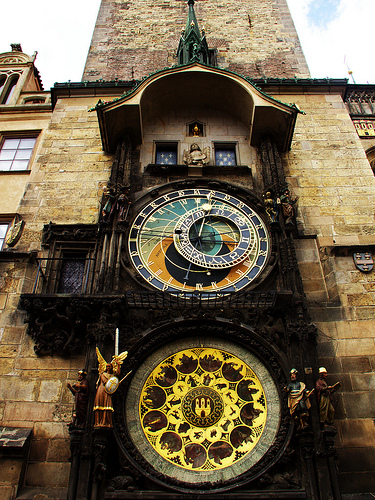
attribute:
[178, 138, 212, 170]
angel — gold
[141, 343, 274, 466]
clock — gold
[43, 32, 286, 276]
castle — huge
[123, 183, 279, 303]
clock — large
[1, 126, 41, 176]
window — closed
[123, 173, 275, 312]
clock — circular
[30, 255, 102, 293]
fence — metal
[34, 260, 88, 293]
fence — small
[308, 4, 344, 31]
sky — blue patch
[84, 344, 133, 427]
people — Miniature